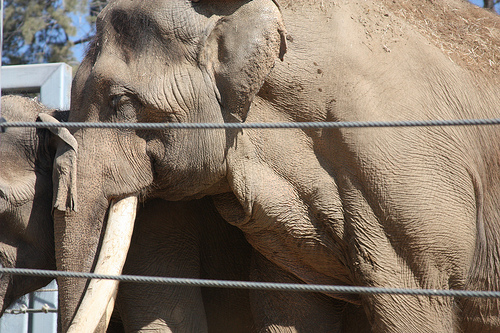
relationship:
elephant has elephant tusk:
[48, 0, 500, 333] [63, 193, 140, 333]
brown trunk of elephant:
[49, 130, 155, 333] [42, 12, 493, 315]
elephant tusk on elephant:
[63, 193, 140, 333] [48, 0, 500, 333]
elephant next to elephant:
[48, 0, 500, 333] [10, 96, 92, 241]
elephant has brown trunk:
[48, 0, 500, 333] [53, 130, 145, 330]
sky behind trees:
[2, 2, 97, 64] [12, 19, 73, 54]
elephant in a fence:
[0, 89, 81, 314] [36, 105, 491, 301]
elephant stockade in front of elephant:
[0, 117, 500, 333] [48, 0, 500, 333]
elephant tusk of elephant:
[63, 193, 140, 333] [48, 0, 500, 333]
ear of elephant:
[204, 1, 292, 181] [48, 0, 500, 333]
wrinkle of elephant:
[142, 54, 204, 134] [48, 0, 500, 333]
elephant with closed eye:
[48, 0, 500, 333] [102, 83, 132, 110]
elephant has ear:
[48, 0, 500, 333] [209, 2, 292, 147]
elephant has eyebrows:
[0, 89, 81, 314] [99, 76, 128, 87]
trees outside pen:
[0, 0, 94, 64] [0, 63, 500, 332]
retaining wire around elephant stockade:
[1, 114, 499, 304] [0, 60, 498, 330]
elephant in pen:
[48, 0, 500, 333] [3, 0, 498, 331]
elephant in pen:
[0, 89, 81, 314] [3, 0, 498, 331]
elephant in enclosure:
[48, 0, 500, 333] [1, 1, 496, 331]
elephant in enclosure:
[3, 89, 81, 316] [1, 1, 496, 331]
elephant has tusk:
[73, 21, 497, 308] [51, 195, 136, 331]